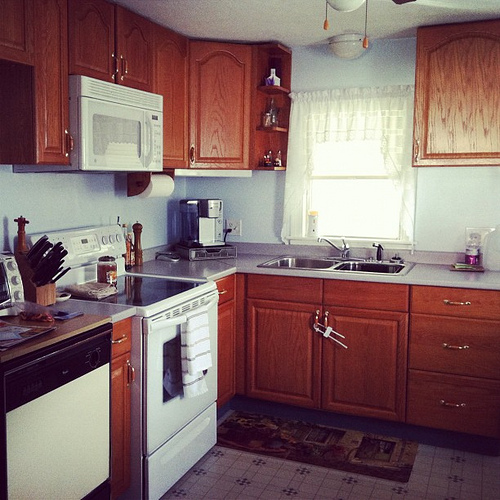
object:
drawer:
[409, 286, 499, 321]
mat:
[215, 408, 419, 484]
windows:
[357, 429, 396, 467]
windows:
[297, 418, 338, 449]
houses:
[232, 409, 409, 477]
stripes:
[183, 328, 212, 386]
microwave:
[12, 73, 163, 175]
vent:
[70, 72, 163, 113]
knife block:
[11, 215, 59, 307]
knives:
[44, 241, 63, 260]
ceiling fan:
[328, 32, 368, 61]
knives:
[33, 241, 53, 257]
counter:
[125, 245, 237, 280]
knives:
[28, 234, 48, 261]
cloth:
[180, 305, 212, 400]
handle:
[443, 300, 472, 306]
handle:
[441, 399, 466, 407]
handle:
[324, 308, 329, 335]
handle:
[122, 55, 129, 77]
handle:
[441, 342, 471, 350]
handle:
[150, 299, 221, 331]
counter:
[0, 299, 135, 361]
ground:
[228, 452, 366, 500]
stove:
[16, 223, 218, 500]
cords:
[323, 3, 370, 50]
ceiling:
[111, 0, 498, 44]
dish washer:
[21, 222, 219, 497]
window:
[286, 85, 415, 245]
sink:
[257, 255, 403, 276]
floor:
[161, 397, 500, 499]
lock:
[314, 322, 348, 350]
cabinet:
[244, 272, 409, 424]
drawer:
[405, 312, 499, 379]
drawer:
[405, 369, 499, 438]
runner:
[219, 409, 407, 474]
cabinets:
[35, 1, 189, 172]